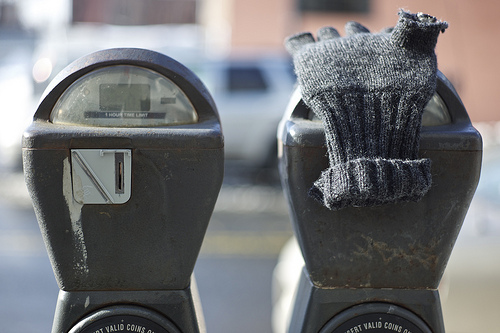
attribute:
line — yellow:
[193, 219, 306, 267]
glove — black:
[282, 8, 454, 215]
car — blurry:
[168, 46, 319, 181]